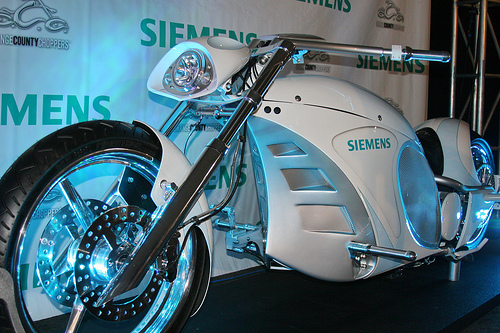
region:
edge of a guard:
[190, 235, 225, 288]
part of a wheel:
[0, 135, 74, 252]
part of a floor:
[278, 284, 311, 311]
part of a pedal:
[380, 245, 411, 272]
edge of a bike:
[332, 184, 371, 260]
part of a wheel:
[79, 215, 142, 294]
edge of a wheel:
[6, 142, 55, 180]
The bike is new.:
[19, 29, 494, 310]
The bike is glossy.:
[8, 17, 495, 317]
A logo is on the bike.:
[327, 127, 402, 161]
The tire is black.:
[0, 112, 215, 328]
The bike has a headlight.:
[141, 40, 238, 107]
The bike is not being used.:
[2, 32, 495, 322]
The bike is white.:
[9, 30, 497, 313]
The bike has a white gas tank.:
[257, 66, 435, 172]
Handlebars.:
[239, 21, 465, 99]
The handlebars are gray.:
[234, 21, 457, 76]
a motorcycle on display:
[24, 11, 497, 308]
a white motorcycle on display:
[25, 23, 497, 313]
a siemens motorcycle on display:
[16, 25, 497, 319]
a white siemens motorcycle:
[19, 15, 469, 332]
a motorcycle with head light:
[24, 27, 495, 297]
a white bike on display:
[25, 28, 497, 291]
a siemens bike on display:
[26, 20, 497, 285]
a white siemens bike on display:
[44, 24, 494, 276]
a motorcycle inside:
[21, 12, 498, 299]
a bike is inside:
[64, 18, 458, 323]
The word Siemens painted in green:
[338, 132, 396, 154]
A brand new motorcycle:
[0, 28, 499, 330]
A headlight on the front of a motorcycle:
[142, 22, 253, 105]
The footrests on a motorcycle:
[209, 200, 419, 280]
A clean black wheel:
[1, 108, 221, 331]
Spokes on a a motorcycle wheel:
[28, 161, 180, 324]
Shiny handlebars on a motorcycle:
[248, 25, 452, 76]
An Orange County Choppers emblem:
[0, 0, 80, 60]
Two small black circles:
[260, 102, 286, 117]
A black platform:
[15, 201, 497, 331]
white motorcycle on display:
[19, 20, 481, 279]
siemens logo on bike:
[327, 122, 388, 164]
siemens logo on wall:
[0, 96, 108, 131]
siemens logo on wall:
[350, 55, 425, 81]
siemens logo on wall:
[310, 0, 355, 25]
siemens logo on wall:
[140, 15, 252, 42]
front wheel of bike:
[11, 135, 239, 316]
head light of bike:
[172, 54, 222, 99]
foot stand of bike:
[353, 240, 413, 262]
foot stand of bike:
[208, 215, 257, 235]